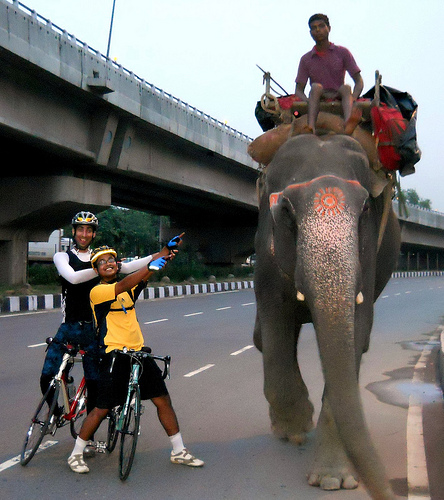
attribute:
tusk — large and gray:
[281, 265, 360, 500]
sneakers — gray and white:
[68, 437, 213, 500]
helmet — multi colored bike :
[73, 206, 102, 227]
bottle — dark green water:
[99, 349, 123, 378]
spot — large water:
[372, 358, 427, 416]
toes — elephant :
[259, 403, 374, 494]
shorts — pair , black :
[92, 342, 171, 399]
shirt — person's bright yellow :
[91, 284, 156, 358]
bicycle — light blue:
[16, 338, 177, 480]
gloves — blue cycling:
[145, 232, 188, 280]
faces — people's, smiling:
[66, 205, 124, 280]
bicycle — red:
[19, 334, 113, 447]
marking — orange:
[306, 180, 347, 226]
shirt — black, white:
[48, 246, 159, 330]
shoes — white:
[63, 448, 208, 477]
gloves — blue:
[139, 229, 187, 276]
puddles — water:
[383, 335, 429, 400]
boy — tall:
[42, 205, 193, 449]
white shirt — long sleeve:
[46, 237, 167, 293]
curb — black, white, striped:
[0, 284, 395, 432]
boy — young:
[64, 230, 204, 473]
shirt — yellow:
[87, 280, 145, 354]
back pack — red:
[369, 100, 419, 172]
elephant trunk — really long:
[297, 216, 394, 497]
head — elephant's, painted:
[261, 136, 392, 326]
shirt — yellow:
[88, 279, 148, 359]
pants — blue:
[39, 320, 97, 413]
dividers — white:
[141, 297, 255, 326]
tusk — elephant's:
[294, 289, 306, 301]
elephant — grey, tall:
[249, 130, 407, 498]